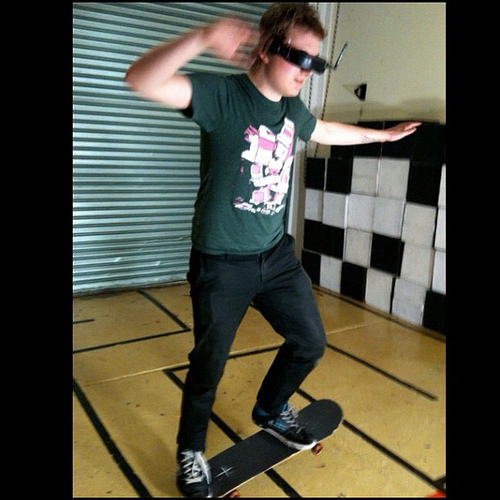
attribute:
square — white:
[301, 188, 346, 228]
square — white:
[316, 190, 349, 227]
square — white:
[349, 157, 384, 198]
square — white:
[370, 159, 410, 204]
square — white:
[347, 191, 378, 235]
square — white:
[369, 195, 407, 238]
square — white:
[341, 229, 374, 264]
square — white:
[315, 255, 345, 291]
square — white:
[361, 269, 394, 317]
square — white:
[391, 279, 426, 329]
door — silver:
[75, 9, 273, 305]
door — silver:
[75, 4, 296, 302]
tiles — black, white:
[298, 121, 445, 311]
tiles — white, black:
[298, 126, 461, 337]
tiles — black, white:
[271, 131, 447, 331]